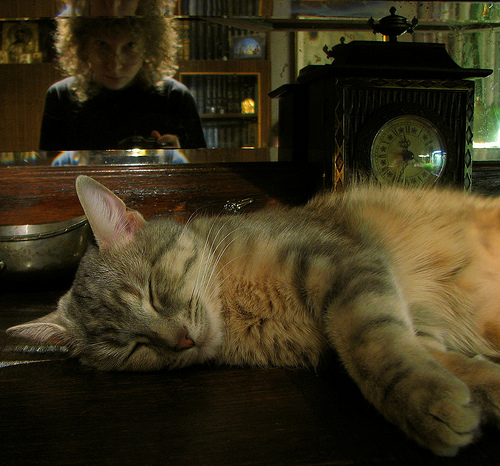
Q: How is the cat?
A: Sleeping.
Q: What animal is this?
A: A cat.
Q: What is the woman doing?
A: Looking at the cat.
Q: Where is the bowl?
A: Behind the cat.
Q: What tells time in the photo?
A: The clock.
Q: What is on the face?
A: Hands.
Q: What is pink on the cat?
A: Its nose.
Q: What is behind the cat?
A: A mirror.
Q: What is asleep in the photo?
A: The kitty.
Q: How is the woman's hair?
A: Curly.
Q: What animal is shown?
A: Cat.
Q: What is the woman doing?
A: Taking a picture of the cat.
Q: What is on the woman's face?
A: Glasses.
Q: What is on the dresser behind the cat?
A: Mirror.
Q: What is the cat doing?
A: Sleeping.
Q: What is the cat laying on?
A: Dresser.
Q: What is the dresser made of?
A: Wood.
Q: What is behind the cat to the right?
A: Clock.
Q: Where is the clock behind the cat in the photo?
A: Clock on the table.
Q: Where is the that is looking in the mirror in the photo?
A: Behind the cat.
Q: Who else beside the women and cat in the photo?
A: No other person or animal in the photo.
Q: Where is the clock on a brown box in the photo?
A: Behind the cat.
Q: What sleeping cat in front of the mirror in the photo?
A: In front of the woman.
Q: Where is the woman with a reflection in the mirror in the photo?
A: Woman near brown table.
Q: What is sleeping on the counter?
A: A cat.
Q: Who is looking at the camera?
A: A woman.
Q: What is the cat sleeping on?
A: A counter.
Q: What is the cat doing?
A: Sleeping.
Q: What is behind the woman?
A: A shelf.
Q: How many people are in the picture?
A: One.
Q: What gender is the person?
A: Female.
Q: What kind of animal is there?
A: A cat.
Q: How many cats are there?
A: One.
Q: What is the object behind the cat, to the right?
A: A clock.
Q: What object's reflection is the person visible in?
A: A mirror.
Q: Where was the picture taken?
A: In a room of a house.